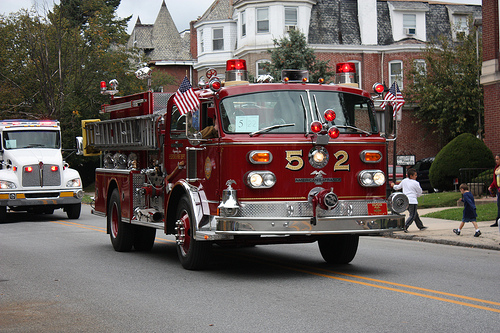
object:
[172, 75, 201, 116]
american flag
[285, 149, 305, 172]
number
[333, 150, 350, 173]
number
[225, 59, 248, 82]
lights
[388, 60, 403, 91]
window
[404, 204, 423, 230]
black pants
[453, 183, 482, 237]
boy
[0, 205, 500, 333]
ground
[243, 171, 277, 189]
lights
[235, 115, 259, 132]
sign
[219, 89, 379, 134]
window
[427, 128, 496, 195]
bush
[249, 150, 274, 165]
light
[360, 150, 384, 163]
light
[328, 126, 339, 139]
light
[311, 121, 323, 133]
light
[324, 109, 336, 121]
light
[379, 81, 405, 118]
flag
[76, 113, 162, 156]
ladder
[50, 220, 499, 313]
lines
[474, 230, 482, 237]
sneakers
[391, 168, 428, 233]
boy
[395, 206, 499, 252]
sidewalk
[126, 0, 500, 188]
house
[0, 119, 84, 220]
vehicle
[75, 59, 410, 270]
fire truck